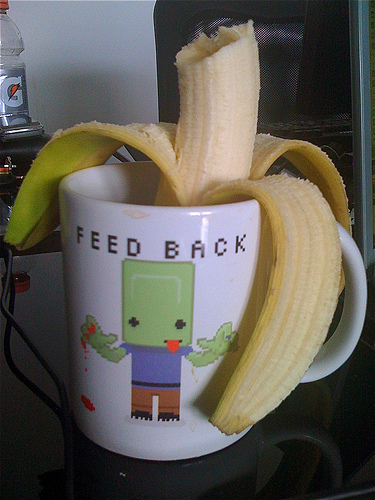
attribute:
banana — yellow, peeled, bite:
[2, 14, 352, 437]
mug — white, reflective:
[62, 161, 369, 463]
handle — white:
[300, 222, 370, 385]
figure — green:
[77, 258, 240, 426]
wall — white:
[9, 3, 163, 160]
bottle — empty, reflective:
[0, 0, 30, 119]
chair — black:
[152, 0, 311, 146]